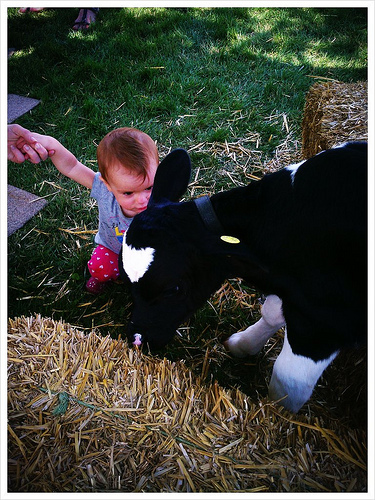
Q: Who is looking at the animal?
A: A baby.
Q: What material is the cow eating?
A: Hay.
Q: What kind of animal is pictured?
A: Cow.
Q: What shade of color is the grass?
A: Green.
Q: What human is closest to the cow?
A: The child.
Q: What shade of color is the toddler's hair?
A: Red.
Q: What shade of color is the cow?
A: Black and white.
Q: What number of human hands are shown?
A: Two.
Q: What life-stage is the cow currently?
A: Calf.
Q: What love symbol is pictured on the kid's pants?
A: Hearts.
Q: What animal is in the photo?
A: A cow.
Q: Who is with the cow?
A: A baby.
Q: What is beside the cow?
A: A bail of hay.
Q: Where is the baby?
A: On the grass.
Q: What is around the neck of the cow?
A: A collar.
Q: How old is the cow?
A: Young.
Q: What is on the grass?
A: A pacifier.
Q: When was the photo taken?
A: During the daytime.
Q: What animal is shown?
A: Cow.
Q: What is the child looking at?
A: Calf.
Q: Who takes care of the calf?
A: Farmer.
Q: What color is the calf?
A: Black and white.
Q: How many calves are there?
A: One.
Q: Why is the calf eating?
A: Hungry.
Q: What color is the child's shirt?
A: Gray.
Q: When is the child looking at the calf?
A: Daytime.